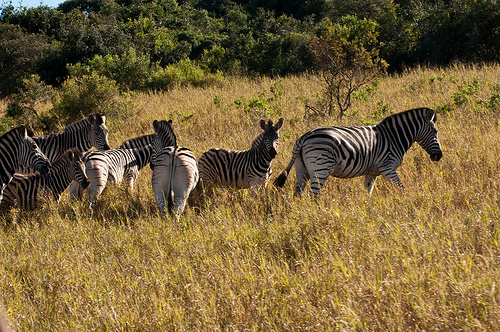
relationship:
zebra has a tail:
[274, 106, 442, 200] [274, 133, 314, 185]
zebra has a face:
[274, 106, 442, 200] [421, 114, 442, 161]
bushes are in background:
[219, 14, 329, 74] [1, 2, 499, 130]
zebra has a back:
[274, 106, 442, 200] [291, 129, 339, 178]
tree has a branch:
[308, 33, 382, 119] [310, 42, 338, 78]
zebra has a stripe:
[274, 106, 442, 200] [335, 125, 364, 160]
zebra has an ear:
[274, 106, 442, 200] [425, 108, 435, 123]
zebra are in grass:
[274, 106, 442, 200] [0, 62, 498, 332]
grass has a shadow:
[0, 62, 498, 332] [248, 63, 496, 74]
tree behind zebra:
[308, 33, 382, 119] [274, 106, 442, 200]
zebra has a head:
[274, 106, 442, 200] [412, 108, 441, 161]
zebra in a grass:
[274, 106, 442, 200] [0, 62, 498, 332]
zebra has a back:
[274, 106, 442, 200] [295, 128, 362, 179]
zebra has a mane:
[274, 106, 442, 200] [374, 107, 437, 131]